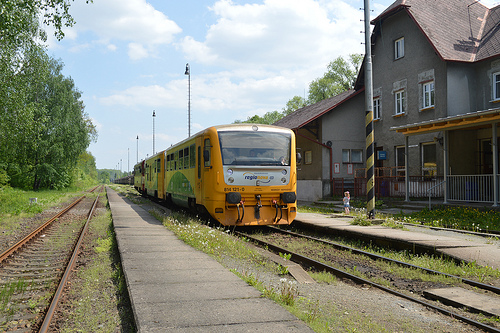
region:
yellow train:
[134, 122, 315, 230]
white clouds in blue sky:
[72, 21, 92, 51]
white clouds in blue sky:
[231, 25, 251, 43]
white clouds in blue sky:
[274, 16, 301, 38]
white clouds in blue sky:
[227, 33, 255, 81]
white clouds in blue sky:
[104, 18, 142, 43]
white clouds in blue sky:
[92, 36, 143, 61]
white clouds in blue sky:
[91, 49, 128, 97]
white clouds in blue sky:
[130, 65, 158, 126]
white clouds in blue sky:
[150, 8, 214, 36]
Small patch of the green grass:
[24, 188, 34, 199]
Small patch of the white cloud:
[262, 22, 292, 42]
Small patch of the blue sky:
[170, 3, 191, 16]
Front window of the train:
[220, 132, 292, 165]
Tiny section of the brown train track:
[57, 256, 79, 286]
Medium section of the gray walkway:
[132, 228, 174, 273]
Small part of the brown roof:
[427, 10, 449, 33]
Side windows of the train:
[176, 149, 191, 167]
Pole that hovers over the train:
[183, 61, 195, 136]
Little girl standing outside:
[341, 187, 353, 215]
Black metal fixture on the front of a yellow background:
[226, 188, 243, 205]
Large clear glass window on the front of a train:
[216, 125, 295, 167]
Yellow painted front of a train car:
[209, 120, 296, 226]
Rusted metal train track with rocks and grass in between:
[8, 229, 68, 324]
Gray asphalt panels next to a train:
[116, 232, 216, 292]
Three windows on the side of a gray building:
[358, 75, 452, 122]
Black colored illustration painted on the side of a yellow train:
[159, 169, 199, 197]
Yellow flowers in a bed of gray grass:
[422, 205, 497, 232]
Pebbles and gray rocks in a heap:
[302, 280, 383, 317]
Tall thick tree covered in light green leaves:
[11, 38, 78, 183]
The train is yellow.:
[127, 121, 304, 227]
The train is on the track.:
[127, 146, 483, 326]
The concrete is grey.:
[107, 158, 286, 329]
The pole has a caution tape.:
[363, 108, 375, 217]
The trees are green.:
[0, 1, 113, 187]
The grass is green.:
[400, 249, 476, 279]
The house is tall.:
[364, 1, 496, 206]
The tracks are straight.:
[3, 160, 111, 327]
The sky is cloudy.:
[69, 11, 299, 101]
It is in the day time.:
[39, 8, 331, 101]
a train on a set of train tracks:
[123, 120, 300, 230]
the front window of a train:
[215, 124, 298, 174]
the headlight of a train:
[224, 173, 241, 188]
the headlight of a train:
[279, 172, 287, 184]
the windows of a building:
[415, 77, 439, 109]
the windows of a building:
[389, 85, 410, 117]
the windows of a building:
[371, 90, 383, 122]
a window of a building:
[387, 31, 412, 62]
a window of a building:
[389, 140, 411, 182]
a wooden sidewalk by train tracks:
[99, 167, 302, 329]